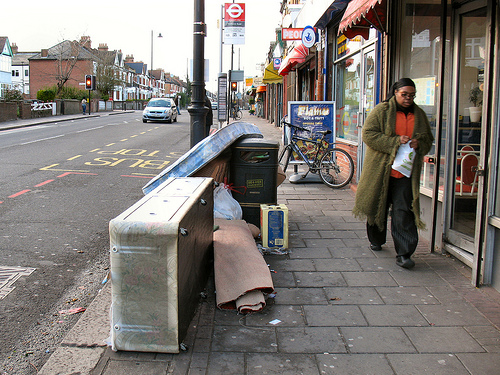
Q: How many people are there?
A: 1.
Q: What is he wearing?
A: Glasses.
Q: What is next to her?
A: A building.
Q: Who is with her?
A: No one.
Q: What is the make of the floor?
A: Bricks.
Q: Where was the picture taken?
A: On the sidewalk.